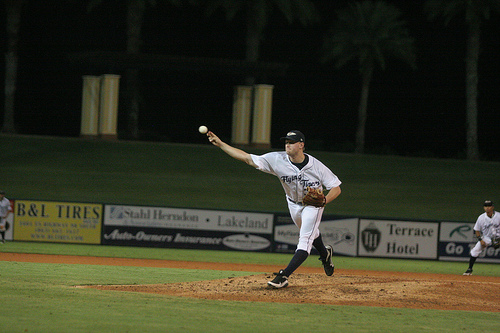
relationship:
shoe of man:
[462, 270, 473, 275] [463, 199, 498, 276]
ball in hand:
[194, 122, 209, 135] [203, 129, 224, 148]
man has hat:
[196, 98, 383, 269] [272, 125, 314, 147]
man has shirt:
[169, 95, 364, 287] [247, 151, 347, 201]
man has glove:
[169, 95, 364, 287] [305, 187, 327, 207]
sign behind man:
[102, 205, 274, 249] [190, 121, 343, 292]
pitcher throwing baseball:
[193, 122, 343, 292] [195, 121, 209, 136]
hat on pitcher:
[272, 125, 314, 147] [193, 122, 343, 292]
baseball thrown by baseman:
[199, 124, 208, 134] [197, 116, 359, 290]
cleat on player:
[262, 272, 293, 290] [203, 127, 343, 292]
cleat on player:
[319, 245, 339, 281] [203, 127, 343, 292]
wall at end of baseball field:
[3, 197, 497, 262] [3, 131, 494, 329]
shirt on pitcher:
[247, 151, 347, 201] [197, 114, 344, 287]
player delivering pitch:
[193, 123, 369, 297] [193, 123, 261, 166]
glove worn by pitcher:
[305, 187, 327, 207] [207, 115, 347, 290]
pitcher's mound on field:
[137, 265, 499, 312] [0, 239, 497, 330]